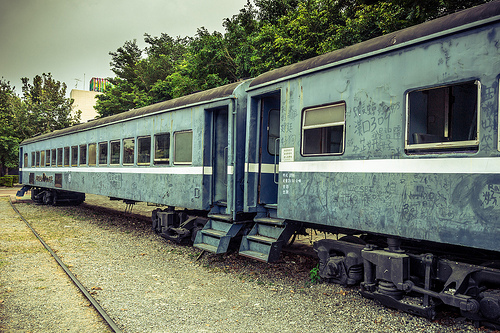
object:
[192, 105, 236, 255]
doorway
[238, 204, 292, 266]
stairs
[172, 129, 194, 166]
windows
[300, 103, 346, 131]
shutters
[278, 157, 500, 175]
stripe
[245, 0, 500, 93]
roof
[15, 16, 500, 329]
trains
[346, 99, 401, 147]
graffiti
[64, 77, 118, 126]
building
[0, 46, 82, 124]
background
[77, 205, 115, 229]
gravel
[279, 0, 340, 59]
trees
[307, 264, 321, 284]
weeds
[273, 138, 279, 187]
handle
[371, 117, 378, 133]
number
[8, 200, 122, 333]
rail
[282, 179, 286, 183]
letters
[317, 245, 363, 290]
wheels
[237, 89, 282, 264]
doorway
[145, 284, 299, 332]
ground